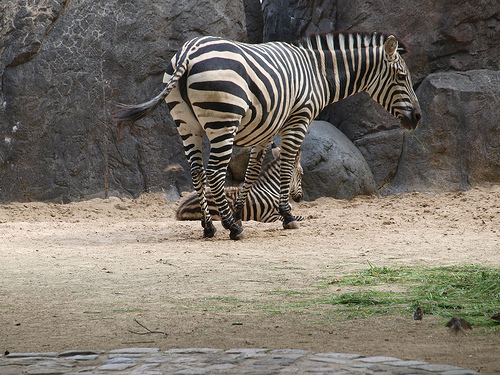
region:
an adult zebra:
[123, 25, 424, 242]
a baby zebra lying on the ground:
[177, 139, 302, 221]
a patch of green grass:
[359, 252, 493, 307]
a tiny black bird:
[409, 295, 431, 327]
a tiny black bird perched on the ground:
[446, 314, 468, 336]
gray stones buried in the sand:
[40, 347, 460, 373]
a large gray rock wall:
[8, 2, 483, 186]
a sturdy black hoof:
[226, 218, 248, 237]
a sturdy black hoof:
[278, 211, 300, 236]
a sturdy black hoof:
[200, 220, 220, 240]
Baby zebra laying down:
[176, 140, 303, 221]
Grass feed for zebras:
[333, 263, 497, 325]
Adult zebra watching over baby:
[111, 33, 422, 239]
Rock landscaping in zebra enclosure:
[1, 2, 497, 192]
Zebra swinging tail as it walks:
[116, 29, 423, 239]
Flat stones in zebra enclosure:
[1, 351, 473, 373]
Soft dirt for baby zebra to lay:
[1, 197, 497, 233]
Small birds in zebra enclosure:
[413, 306, 473, 336]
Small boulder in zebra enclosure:
[225, 115, 375, 190]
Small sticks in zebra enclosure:
[120, 317, 171, 347]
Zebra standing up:
[111, 30, 429, 255]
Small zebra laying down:
[179, 146, 320, 228]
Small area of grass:
[323, 243, 499, 346]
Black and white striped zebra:
[107, 46, 202, 138]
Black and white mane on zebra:
[289, 25, 425, 60]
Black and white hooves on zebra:
[178, 205, 311, 246]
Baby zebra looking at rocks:
[159, 130, 298, 235]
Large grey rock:
[232, 96, 387, 211]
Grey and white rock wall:
[4, 3, 498, 212]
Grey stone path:
[0, 343, 488, 373]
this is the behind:
[159, 77, 221, 137]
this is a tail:
[110, 9, 191, 153]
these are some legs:
[208, 146, 277, 222]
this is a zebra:
[260, 38, 312, 168]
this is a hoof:
[189, 118, 245, 228]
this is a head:
[339, 2, 492, 197]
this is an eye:
[390, 56, 414, 84]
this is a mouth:
[339, 112, 426, 139]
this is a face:
[378, 54, 403, 86]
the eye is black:
[372, 30, 429, 100]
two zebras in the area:
[152, 48, 399, 248]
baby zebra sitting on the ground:
[170, 156, 302, 221]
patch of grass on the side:
[355, 254, 497, 343]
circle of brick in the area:
[97, 356, 383, 374]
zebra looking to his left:
[357, 29, 432, 137]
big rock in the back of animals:
[313, 74, 488, 206]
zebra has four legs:
[170, 152, 305, 240]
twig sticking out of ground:
[74, 17, 121, 214]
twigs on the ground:
[96, 311, 179, 349]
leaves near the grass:
[384, 303, 476, 337]